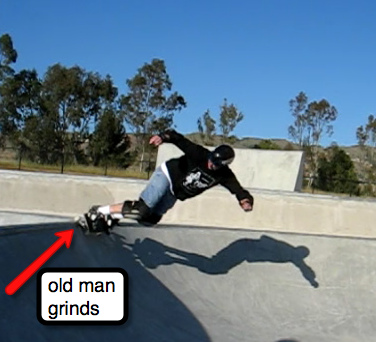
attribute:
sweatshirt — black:
[161, 126, 250, 215]